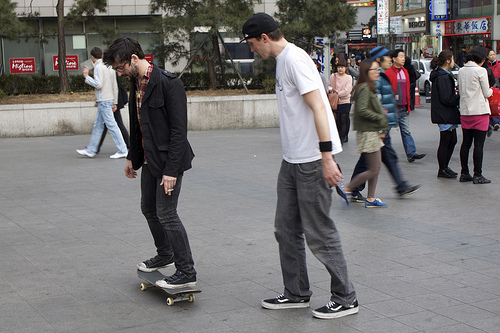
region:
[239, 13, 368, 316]
Male watching the skateboard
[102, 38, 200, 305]
Male on a skateboard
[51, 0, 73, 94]
Brown tree stem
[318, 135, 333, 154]
Black wristband worn by the male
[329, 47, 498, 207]
Group of pedestrians walking around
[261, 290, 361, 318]
Pair of Nike sneakers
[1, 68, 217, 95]
Row of trimmed bush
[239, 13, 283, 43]
Black hat worn by the male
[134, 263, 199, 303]
Black skateboard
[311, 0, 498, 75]
Several buildings on the side of the road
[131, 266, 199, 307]
a skateboard under a man's feet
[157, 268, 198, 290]
a man's black and white shoe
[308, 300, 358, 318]
a man's black and white shoe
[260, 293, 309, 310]
a man's black and white shoe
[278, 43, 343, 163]
a man's white t shirt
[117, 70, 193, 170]
a man's black jacket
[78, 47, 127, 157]
two people are walking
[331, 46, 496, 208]
a crowd of people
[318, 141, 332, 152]
a black wristband on a mn's wrist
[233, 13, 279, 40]
a black hat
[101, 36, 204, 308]
a man standing on a skateboard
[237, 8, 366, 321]
a man standing on the sidewalk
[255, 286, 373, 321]
black shoes with with soles and shoestrings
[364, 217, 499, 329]
square patterned walkway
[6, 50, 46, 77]
red sign with white writting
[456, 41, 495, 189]
woman wearing a pink skirt and white coat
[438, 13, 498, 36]
white sign with oriental writting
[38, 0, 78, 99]
tree trunk planted in front of a building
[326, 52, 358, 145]
woman carrying a brown bag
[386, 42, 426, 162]
man wearing a red coat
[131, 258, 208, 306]
black grip tape on board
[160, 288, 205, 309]
white wheels on bottom of board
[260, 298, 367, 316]
black and white shoes on feet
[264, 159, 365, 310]
black pants on man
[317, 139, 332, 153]
black wrist band on man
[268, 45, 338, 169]
white t-shirt on man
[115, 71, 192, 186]
black blazer on man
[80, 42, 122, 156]
man walking on street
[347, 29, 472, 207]
people walking on street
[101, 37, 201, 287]
a person on a skateboard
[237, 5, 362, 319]
a person in a white shirt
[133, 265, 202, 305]
a skateboard on the ground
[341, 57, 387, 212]
a woman in a green jacket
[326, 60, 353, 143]
a woman in a pink shirt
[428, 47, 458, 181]
a woman in a black jacket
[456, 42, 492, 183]
a woman in a white jacket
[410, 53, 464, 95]
a white car on the road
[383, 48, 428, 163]
a man in a red jacket